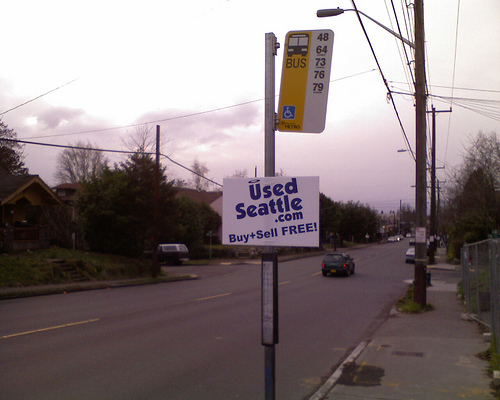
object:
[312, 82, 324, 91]
79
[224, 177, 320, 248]
sign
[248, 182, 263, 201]
letters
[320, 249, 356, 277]
car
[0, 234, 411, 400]
street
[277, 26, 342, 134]
sign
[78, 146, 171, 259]
tree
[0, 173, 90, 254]
house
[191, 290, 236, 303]
line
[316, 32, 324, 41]
4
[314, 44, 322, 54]
6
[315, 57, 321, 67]
7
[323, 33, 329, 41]
8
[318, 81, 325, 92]
9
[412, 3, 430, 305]
electrical pole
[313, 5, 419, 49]
street lights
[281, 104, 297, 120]
handicap placard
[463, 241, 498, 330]
fence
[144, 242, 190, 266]
vehicle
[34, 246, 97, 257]
grass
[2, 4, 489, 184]
sky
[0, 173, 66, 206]
roof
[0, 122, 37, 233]
trees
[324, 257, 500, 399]
sidewalk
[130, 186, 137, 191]
leaves